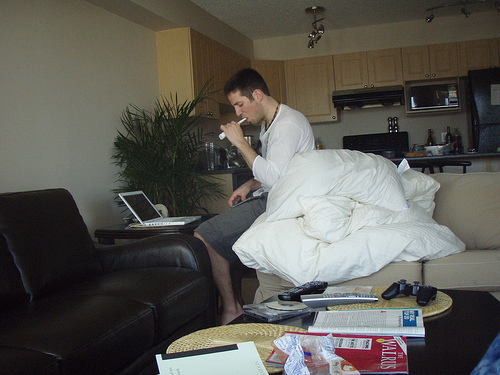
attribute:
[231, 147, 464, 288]
linens — white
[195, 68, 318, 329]
man — brushing his teeth, taking temperature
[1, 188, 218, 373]
sofa — black, dark colored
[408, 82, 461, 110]
microwave oven — black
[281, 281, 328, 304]
remote control — black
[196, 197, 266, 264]
shorts — gray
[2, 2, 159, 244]
wall — white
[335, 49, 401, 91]
cabinet — brown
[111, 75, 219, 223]
plant — large, green, potted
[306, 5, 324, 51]
light — off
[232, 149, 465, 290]
blanket — white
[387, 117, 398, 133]
salt&pepper shakers — silver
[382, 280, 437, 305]
remote — for a gaming system, black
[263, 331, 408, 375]
valrus magazine — red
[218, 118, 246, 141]
thermometer — white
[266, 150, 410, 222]
pillows — white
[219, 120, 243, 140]
toothbrush — white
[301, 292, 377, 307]
remote — gray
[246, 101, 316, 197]
shirt — white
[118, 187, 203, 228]
computer — white, open, laptop